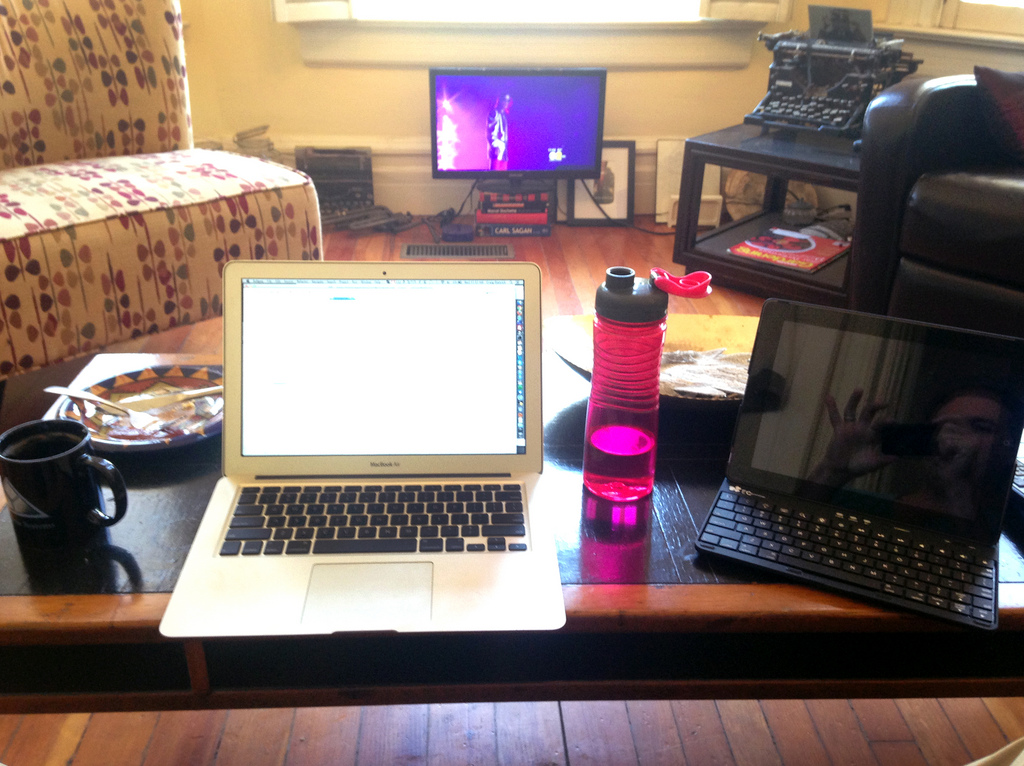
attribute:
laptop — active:
[159, 249, 581, 635]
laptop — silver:
[699, 285, 1014, 628]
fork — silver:
[49, 382, 179, 431]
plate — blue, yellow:
[57, 359, 251, 449]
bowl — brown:
[560, 326, 780, 409]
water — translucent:
[570, 424, 668, 498]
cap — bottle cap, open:
[646, 265, 714, 300]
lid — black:
[598, 265, 684, 323]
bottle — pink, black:
[590, 259, 712, 513]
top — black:
[585, 262, 672, 326]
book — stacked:
[464, 182, 554, 205]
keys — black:
[214, 478, 534, 565]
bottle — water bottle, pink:
[577, 257, 675, 548]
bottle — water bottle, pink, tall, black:
[574, 254, 677, 512]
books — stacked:
[471, 180, 565, 226]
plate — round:
[59, 359, 224, 452]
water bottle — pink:
[577, 262, 711, 537]